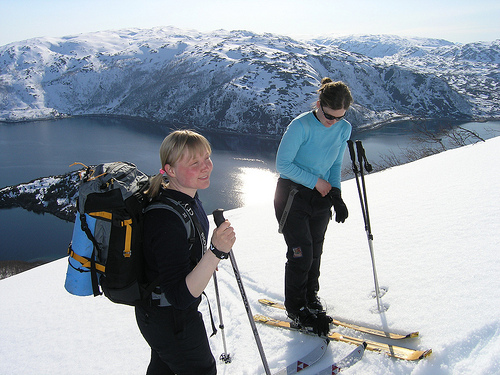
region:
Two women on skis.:
[57, 75, 427, 373]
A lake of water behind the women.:
[0, 101, 498, 281]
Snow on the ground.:
[3, 128, 498, 373]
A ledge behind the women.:
[1, 131, 496, 281]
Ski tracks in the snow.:
[215, 226, 290, 316]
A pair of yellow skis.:
[250, 293, 433, 359]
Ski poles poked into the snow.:
[343, 137, 391, 314]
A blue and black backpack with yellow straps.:
[65, 159, 145, 304]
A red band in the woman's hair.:
[150, 162, 170, 177]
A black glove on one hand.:
[309, 176, 349, 224]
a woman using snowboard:
[258, 286, 425, 361]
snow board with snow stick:
[348, 136, 405, 363]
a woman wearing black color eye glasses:
[316, 98, 353, 123]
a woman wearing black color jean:
[268, 184, 337, 332]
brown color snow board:
[255, 310, 425, 350]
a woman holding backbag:
[68, 147, 183, 325]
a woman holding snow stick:
[206, 195, 271, 373]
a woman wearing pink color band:
[150, 165, 166, 175]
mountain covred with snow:
[96, 25, 288, 122]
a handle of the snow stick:
[211, 205, 238, 272]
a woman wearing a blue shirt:
[267, 77, 371, 344]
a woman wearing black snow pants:
[257, 75, 379, 356]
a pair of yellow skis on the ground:
[251, 295, 433, 372]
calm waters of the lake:
[55, 113, 133, 150]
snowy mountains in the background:
[41, 6, 290, 98]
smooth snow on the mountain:
[408, 193, 473, 269]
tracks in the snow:
[413, 294, 498, 374]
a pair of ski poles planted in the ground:
[343, 145, 417, 330]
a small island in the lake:
[15, 164, 118, 224]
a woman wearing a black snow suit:
[89, 137, 250, 373]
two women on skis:
[59, 70, 429, 372]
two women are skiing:
[62, 60, 454, 359]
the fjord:
[19, 23, 495, 168]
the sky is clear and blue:
[31, 2, 98, 22]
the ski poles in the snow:
[328, 138, 412, 314]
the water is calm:
[31, 129, 108, 151]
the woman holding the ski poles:
[90, 135, 319, 374]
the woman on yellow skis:
[257, 80, 452, 357]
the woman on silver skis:
[82, 126, 365, 367]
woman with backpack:
[52, 152, 238, 335]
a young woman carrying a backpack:
[65, 178, 146, 305]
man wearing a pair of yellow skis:
[253, 295, 432, 364]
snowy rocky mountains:
[0, 24, 499, 136]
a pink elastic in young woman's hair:
[156, 163, 168, 179]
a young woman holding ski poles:
[203, 210, 271, 373]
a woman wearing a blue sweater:
[276, 111, 352, 196]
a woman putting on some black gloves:
[314, 177, 349, 225]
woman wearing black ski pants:
[274, 179, 336, 313]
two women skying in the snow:
[69, 78, 430, 373]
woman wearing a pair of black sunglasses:
[316, 100, 347, 122]